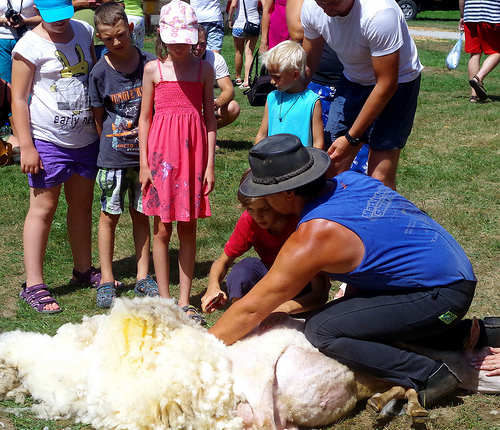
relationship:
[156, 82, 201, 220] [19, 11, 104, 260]
pink dress on girl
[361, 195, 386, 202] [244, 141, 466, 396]
blue shirt on man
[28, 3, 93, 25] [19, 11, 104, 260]
blue cap on girl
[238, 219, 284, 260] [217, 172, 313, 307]
red shirt on boy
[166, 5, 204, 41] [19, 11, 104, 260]
pink hat on girl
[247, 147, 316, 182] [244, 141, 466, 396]
hat on man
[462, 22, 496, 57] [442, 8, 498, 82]
red shorts on person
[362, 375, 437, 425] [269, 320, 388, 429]
hooves of sheep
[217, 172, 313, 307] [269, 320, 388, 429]
boy shearing sheep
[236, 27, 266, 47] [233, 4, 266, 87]
blue shorts on woman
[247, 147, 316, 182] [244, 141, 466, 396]
hat of man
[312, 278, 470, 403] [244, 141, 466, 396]
pants on man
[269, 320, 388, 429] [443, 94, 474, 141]
sheep on grass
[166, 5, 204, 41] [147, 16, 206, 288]
pink hat of skinny girl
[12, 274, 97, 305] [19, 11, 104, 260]
purple sandals on girl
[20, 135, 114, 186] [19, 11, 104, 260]
purple shorts on girl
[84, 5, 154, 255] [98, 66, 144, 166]
kid in dark blue shirt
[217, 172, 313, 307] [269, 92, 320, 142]
boy in light blue shirt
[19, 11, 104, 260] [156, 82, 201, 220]
girl in pink dress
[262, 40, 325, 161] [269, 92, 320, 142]
boy in light blue shirt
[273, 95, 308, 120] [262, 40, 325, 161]
necklace on boy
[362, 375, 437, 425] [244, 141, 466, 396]
hooves under man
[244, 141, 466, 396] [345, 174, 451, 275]
man in blue shirt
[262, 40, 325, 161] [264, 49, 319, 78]
boy with blonde hair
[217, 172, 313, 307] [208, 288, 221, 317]
boy holding scissors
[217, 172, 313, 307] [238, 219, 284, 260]
boy in red shirt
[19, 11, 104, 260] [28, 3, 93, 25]
girl in blue cap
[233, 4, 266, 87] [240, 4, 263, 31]
woman in white shirt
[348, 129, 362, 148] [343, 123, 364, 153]
watch on a wrist